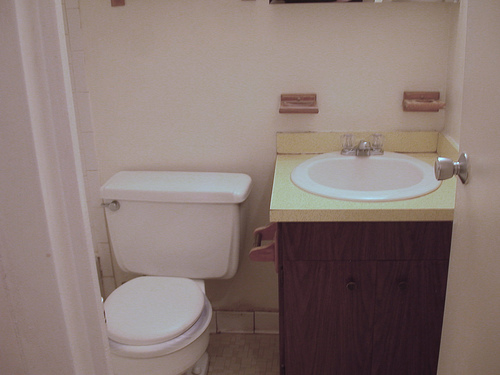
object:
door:
[460, 40, 499, 343]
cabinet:
[275, 224, 453, 375]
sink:
[296, 149, 433, 199]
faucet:
[333, 133, 392, 156]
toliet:
[96, 264, 221, 373]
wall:
[135, 28, 239, 96]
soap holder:
[269, 87, 322, 116]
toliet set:
[29, 59, 436, 373]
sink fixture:
[283, 133, 436, 211]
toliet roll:
[246, 220, 272, 264]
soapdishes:
[279, 79, 447, 117]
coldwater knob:
[337, 130, 355, 155]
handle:
[451, 154, 474, 184]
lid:
[105, 286, 200, 329]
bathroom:
[39, 40, 473, 257]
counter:
[269, 193, 316, 216]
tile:
[239, 308, 256, 326]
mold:
[243, 307, 260, 313]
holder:
[263, 244, 279, 262]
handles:
[333, 132, 387, 141]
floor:
[226, 337, 272, 372]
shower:
[15, 85, 80, 250]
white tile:
[78, 155, 98, 205]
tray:
[281, 103, 315, 113]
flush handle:
[99, 195, 123, 209]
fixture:
[350, 147, 373, 154]